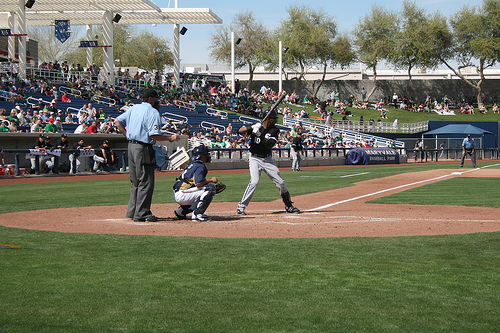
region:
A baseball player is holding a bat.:
[233, 85, 310, 222]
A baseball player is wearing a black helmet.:
[260, 104, 279, 121]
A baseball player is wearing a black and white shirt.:
[244, 119, 282, 163]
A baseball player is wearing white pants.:
[233, 150, 293, 213]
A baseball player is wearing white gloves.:
[247, 118, 262, 136]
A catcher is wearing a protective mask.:
[191, 139, 212, 164]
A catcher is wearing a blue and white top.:
[167, 158, 211, 192]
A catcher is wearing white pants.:
[168, 185, 217, 222]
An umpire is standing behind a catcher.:
[106, 83, 183, 229]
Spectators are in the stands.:
[0, 54, 406, 178]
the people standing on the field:
[110, 87, 477, 222]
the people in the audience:
[1, 59, 498, 158]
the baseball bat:
[248, 90, 288, 138]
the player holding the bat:
[234, 109, 300, 216]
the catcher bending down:
[173, 144, 223, 222]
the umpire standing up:
[115, 89, 180, 222]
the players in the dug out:
[29, 134, 116, 170]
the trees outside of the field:
[8, 2, 498, 114]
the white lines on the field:
[80, 162, 498, 224]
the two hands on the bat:
[252, 121, 262, 136]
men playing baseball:
[64, 32, 489, 309]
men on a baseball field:
[65, 40, 442, 329]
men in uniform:
[119, 84, 390, 269]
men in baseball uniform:
[47, 62, 484, 327]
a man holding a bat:
[205, 65, 414, 270]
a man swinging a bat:
[237, 94, 367, 254]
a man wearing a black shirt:
[196, 68, 374, 269]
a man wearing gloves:
[179, 61, 360, 276]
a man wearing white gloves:
[229, 93, 330, 188]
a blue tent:
[372, 84, 497, 211]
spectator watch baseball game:
[46, 115, 57, 131]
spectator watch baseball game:
[74, 118, 87, 132]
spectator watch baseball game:
[7, 108, 17, 122]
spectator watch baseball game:
[226, 121, 234, 133]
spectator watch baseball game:
[78, 104, 88, 115]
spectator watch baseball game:
[86, 101, 97, 115]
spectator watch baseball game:
[58, 88, 73, 103]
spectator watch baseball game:
[38, 81, 50, 93]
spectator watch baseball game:
[364, 138, 371, 146]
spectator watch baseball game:
[307, 123, 320, 133]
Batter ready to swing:
[237, 90, 298, 214]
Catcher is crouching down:
[174, 146, 223, 222]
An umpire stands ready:
[461, 134, 475, 166]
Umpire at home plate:
[115, 89, 180, 222]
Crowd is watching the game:
[2, 60, 498, 146]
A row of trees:
[26, 1, 498, 109]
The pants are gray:
[240, 154, 290, 209]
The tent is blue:
[422, 124, 487, 136]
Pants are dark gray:
[126, 143, 153, 220]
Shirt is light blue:
[118, 101, 160, 143]